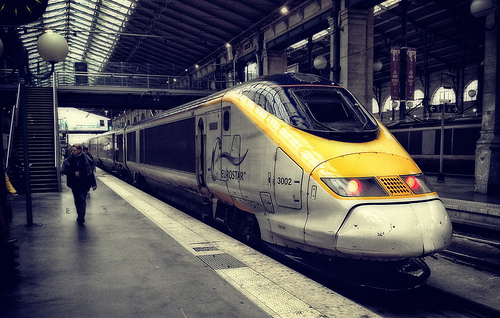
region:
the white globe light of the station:
[37, 31, 68, 63]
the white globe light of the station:
[465, 86, 476, 97]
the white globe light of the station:
[404, 101, 413, 107]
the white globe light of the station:
[390, 100, 398, 110]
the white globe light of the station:
[311, 55, 326, 66]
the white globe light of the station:
[374, 60, 384, 72]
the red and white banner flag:
[390, 47, 400, 99]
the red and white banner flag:
[404, 48, 416, 99]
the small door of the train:
[273, 148, 303, 203]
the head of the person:
[69, 145, 82, 152]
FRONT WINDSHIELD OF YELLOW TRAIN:
[244, 70, 387, 145]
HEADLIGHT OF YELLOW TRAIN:
[331, 174, 375, 196]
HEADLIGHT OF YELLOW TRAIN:
[404, 170, 436, 200]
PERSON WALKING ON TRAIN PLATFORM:
[61, 138, 99, 233]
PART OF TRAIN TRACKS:
[467, 220, 497, 272]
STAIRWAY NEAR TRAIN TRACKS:
[9, 77, 61, 200]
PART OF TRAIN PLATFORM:
[126, 200, 175, 279]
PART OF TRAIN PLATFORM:
[13, 263, 69, 311]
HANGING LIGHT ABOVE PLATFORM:
[33, 29, 73, 69]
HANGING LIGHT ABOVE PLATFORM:
[272, 3, 294, 20]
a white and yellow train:
[76, 73, 453, 297]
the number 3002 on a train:
[274, 172, 295, 187]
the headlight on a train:
[318, 173, 388, 202]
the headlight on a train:
[395, 172, 441, 195]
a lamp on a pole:
[32, 30, 71, 67]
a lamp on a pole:
[468, 0, 496, 21]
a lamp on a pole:
[308, 54, 330, 72]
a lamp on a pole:
[370, 57, 384, 73]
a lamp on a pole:
[465, 88, 477, 98]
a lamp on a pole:
[405, 99, 414, 109]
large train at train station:
[100, 58, 475, 309]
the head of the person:
[69, 143, 81, 156]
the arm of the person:
[60, 158, 74, 176]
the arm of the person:
[83, 154, 98, 187]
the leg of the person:
[72, 186, 84, 222]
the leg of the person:
[76, 185, 87, 222]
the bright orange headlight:
[346, 180, 358, 195]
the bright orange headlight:
[405, 176, 416, 188]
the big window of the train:
[297, 86, 349, 125]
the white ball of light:
[37, 31, 68, 63]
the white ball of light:
[310, 54, 327, 69]